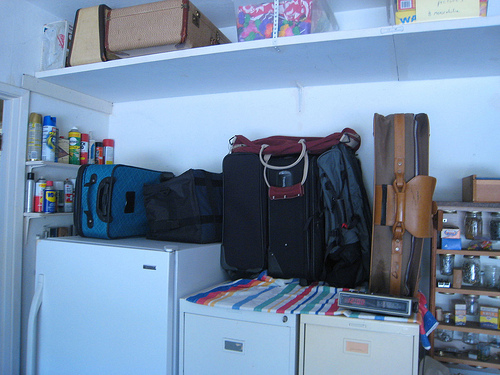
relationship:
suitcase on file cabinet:
[367, 113, 435, 299] [188, 266, 433, 371]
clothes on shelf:
[232, 1, 343, 38] [228, 33, 393, 90]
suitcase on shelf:
[105, 0, 232, 61] [25, 16, 497, 104]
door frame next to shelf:
[2, 84, 30, 374] [22, 157, 82, 176]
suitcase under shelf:
[217, 126, 371, 287] [25, 16, 497, 104]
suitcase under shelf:
[360, 108, 442, 309] [25, 16, 497, 104]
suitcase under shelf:
[138, 164, 226, 244] [25, 16, 497, 104]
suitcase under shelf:
[68, 161, 176, 239] [25, 16, 497, 104]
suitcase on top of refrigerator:
[72, 163, 176, 240] [29, 241, 167, 370]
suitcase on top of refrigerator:
[142, 168, 222, 243] [29, 241, 167, 370]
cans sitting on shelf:
[26, 110, 116, 162] [21, 152, 83, 227]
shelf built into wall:
[30, 158, 96, 171] [22, 80, 111, 235]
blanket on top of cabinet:
[213, 270, 328, 333] [177, 296, 279, 373]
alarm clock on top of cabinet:
[323, 284, 423, 319] [303, 317, 419, 374]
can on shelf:
[26, 112, 42, 161] [22, 155, 87, 170]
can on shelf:
[34, 112, 54, 144] [26, 156, 115, 181]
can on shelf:
[65, 121, 83, 164] [24, 150, 120, 186]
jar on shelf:
[463, 255, 482, 284] [49, 7, 499, 179]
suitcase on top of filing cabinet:
[224, 143, 356, 273] [202, 277, 364, 374]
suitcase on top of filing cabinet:
[367, 113, 435, 299] [202, 277, 364, 374]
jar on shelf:
[463, 292, 480, 324] [439, 250, 499, 252]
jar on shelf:
[459, 250, 477, 282] [439, 250, 499, 252]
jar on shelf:
[439, 252, 454, 278] [439, 250, 499, 252]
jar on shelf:
[484, 255, 498, 286] [439, 250, 499, 252]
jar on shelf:
[464, 210, 481, 240] [439, 250, 499, 252]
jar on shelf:
[485, 210, 497, 245] [439, 250, 499, 252]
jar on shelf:
[438, 209, 461, 249] [437, 293, 498, 294]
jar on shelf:
[449, 299, 466, 328] [432, 327, 498, 329]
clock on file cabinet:
[338, 290, 418, 317] [298, 312, 419, 372]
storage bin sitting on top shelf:
[225, 1, 355, 36] [30, 0, 498, 99]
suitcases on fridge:
[63, 92, 472, 289] [20, 234, 219, 375]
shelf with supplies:
[432, 197, 499, 369] [440, 209, 497, 358]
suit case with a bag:
[217, 148, 272, 283] [229, 124, 361, 199]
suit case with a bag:
[311, 140, 371, 293] [229, 124, 361, 199]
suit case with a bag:
[261, 152, 318, 294] [229, 124, 361, 199]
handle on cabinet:
[214, 335, 251, 357] [177, 272, 300, 372]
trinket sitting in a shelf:
[464, 210, 481, 240] [428, 202, 498, 368]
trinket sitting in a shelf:
[467, 236, 492, 250] [428, 202, 498, 368]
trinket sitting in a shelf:
[435, 277, 452, 287] [428, 202, 498, 368]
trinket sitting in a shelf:
[443, 309, 451, 326] [428, 202, 498, 368]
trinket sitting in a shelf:
[475, 269, 487, 286] [428, 202, 498, 368]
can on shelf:
[34, 175, 49, 217] [23, 159, 96, 221]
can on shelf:
[40, 177, 59, 212] [24, 203, 73, 224]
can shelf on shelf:
[93, 131, 123, 168] [25, 159, 85, 178]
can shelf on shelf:
[68, 123, 90, 158] [25, 159, 85, 178]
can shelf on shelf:
[39, 111, 63, 169] [25, 159, 85, 178]